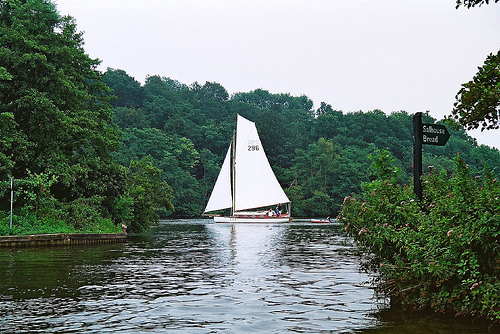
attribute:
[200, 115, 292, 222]
boat — white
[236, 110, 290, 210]
sail — white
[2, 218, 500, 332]
water — calm, body, part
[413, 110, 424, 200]
pole — wooden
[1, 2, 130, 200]
leaves — green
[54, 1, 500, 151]
clouds — white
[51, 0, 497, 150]
sky — blue